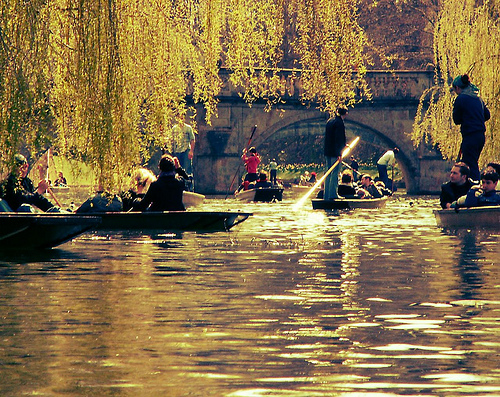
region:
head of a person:
[153, 140, 183, 173]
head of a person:
[13, 148, 28, 177]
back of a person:
[151, 175, 190, 220]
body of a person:
[451, 86, 488, 147]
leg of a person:
[322, 160, 345, 205]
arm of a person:
[238, 150, 250, 164]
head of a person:
[245, 140, 262, 158]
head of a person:
[436, 151, 477, 187]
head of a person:
[475, 159, 499, 188]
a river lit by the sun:
[0, 188, 499, 395]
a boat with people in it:
[431, 204, 498, 230]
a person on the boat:
[463, 165, 498, 207]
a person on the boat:
[438, 161, 478, 208]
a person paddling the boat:
[451, 73, 490, 180]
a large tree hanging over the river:
[0, 0, 407, 207]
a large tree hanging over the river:
[402, 0, 498, 175]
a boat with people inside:
[0, 214, 102, 249]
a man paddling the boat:
[4, 153, 73, 213]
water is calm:
[144, 259, 391, 391]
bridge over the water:
[181, 66, 463, 108]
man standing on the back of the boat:
[296, 90, 381, 220]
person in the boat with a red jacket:
[237, 141, 267, 180]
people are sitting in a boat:
[437, 163, 499, 233]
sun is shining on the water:
[277, 193, 327, 226]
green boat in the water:
[110, 203, 252, 258]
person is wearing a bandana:
[448, 75, 473, 90]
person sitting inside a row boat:
[136, 145, 192, 219]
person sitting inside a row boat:
[0, 151, 60, 216]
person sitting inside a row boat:
[239, 145, 264, 187]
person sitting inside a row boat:
[357, 170, 384, 197]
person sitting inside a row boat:
[434, 160, 472, 210]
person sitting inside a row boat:
[462, 169, 498, 208]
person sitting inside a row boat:
[303, 169, 323, 186]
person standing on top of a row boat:
[320, 102, 352, 205]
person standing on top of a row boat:
[442, 65, 492, 207]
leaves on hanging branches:
[0, 3, 375, 193]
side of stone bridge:
[176, 68, 452, 190]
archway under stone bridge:
[242, 115, 417, 197]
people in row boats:
[0, 143, 495, 258]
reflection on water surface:
[9, 195, 498, 395]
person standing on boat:
[316, 105, 361, 204]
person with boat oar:
[224, 123, 261, 196]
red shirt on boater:
[243, 155, 261, 172]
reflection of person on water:
[314, 212, 349, 335]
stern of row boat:
[254, 186, 282, 201]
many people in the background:
[11, 13, 498, 348]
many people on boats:
[11, 16, 497, 263]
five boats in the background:
[0, 79, 494, 276]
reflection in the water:
[49, 108, 484, 305]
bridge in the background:
[136, 42, 496, 175]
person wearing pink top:
[226, 118, 333, 246]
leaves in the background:
[12, 5, 259, 196]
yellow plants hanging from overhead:
[3, 1, 63, 128]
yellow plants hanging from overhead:
[54, 3, 113, 160]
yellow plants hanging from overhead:
[106, 4, 162, 155]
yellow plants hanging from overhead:
[158, 0, 218, 143]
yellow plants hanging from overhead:
[202, 3, 265, 113]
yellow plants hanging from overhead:
[249, 2, 306, 112]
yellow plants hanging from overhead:
[417, 4, 474, 164]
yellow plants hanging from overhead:
[469, 3, 499, 167]